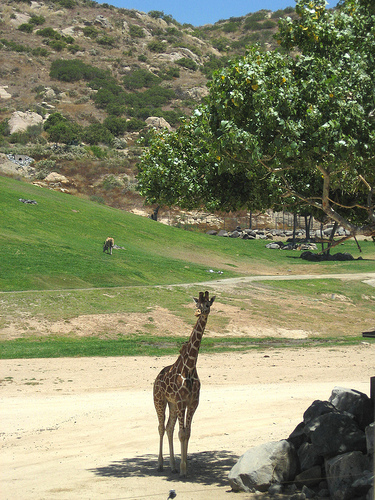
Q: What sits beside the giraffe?
A: Rocks.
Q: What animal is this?
A: Giraffe.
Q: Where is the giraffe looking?
A: Camera.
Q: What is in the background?
A: Mountains.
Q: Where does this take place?
A: Zoo.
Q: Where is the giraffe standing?
A: In the shade.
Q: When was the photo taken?
A: Daytime.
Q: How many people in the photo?
A: None.